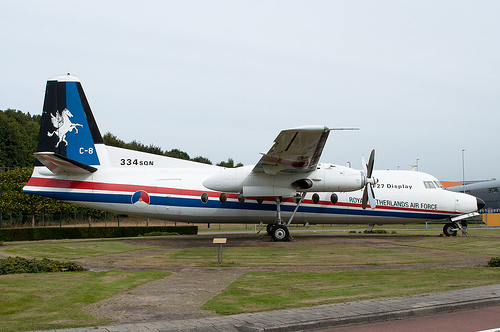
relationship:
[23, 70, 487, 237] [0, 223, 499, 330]
airplane on ground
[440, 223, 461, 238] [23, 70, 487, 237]
front wheel of airplane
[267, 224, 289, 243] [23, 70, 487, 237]
back wheel of airplane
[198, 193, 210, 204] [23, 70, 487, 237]
window on airplane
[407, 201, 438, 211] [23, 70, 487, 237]
letters on airplane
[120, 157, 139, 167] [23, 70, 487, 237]
numbers on airplane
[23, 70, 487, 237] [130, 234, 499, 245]
airplane on landing strip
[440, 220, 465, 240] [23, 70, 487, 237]
front wheel of airplane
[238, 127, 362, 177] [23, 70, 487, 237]
right wing of airplane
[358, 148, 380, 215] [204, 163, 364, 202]
propellor in front of engine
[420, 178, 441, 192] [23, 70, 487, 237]
cockpit of airplane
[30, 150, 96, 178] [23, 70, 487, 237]
horizontal stabilizer of airplane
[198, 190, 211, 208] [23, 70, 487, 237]
window of airplane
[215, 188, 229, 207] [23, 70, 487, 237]
window of airplane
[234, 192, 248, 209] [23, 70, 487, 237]
window of airplane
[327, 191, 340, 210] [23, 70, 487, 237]
window of airplane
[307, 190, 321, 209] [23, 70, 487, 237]
window of airplane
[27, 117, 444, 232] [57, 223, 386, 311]
airplane on ground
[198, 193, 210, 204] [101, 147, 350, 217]
window on plane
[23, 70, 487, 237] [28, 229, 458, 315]
airplane on ground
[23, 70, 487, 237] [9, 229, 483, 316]
airplane on ground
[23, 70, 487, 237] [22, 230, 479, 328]
airplane on ground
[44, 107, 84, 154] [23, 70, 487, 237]
logo on airplane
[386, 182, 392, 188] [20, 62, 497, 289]
letter on plane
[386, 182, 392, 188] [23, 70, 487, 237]
letter on airplane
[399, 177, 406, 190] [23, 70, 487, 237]
letter on airplane